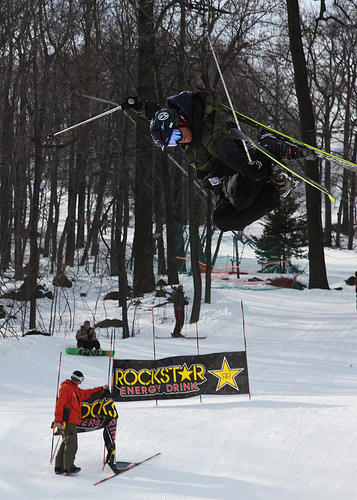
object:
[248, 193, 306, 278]
tree